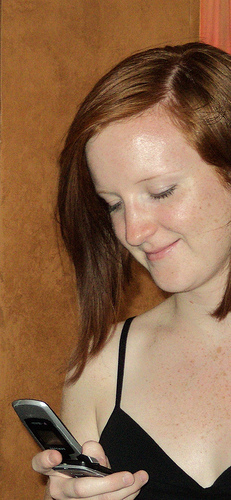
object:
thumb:
[80, 439, 107, 470]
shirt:
[97, 317, 231, 500]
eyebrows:
[97, 190, 115, 197]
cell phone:
[11, 398, 112, 480]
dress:
[98, 314, 231, 499]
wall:
[2, 8, 114, 100]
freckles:
[138, 126, 229, 452]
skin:
[31, 104, 229, 499]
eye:
[149, 183, 176, 199]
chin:
[149, 250, 196, 294]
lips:
[143, 237, 180, 263]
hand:
[31, 450, 150, 500]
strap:
[114, 317, 138, 413]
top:
[98, 315, 231, 499]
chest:
[95, 323, 229, 498]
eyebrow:
[135, 174, 163, 185]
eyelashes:
[149, 185, 176, 200]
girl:
[32, 42, 230, 498]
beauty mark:
[198, 205, 201, 210]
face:
[85, 113, 231, 286]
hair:
[52, 42, 229, 389]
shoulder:
[61, 293, 175, 409]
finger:
[30, 448, 62, 475]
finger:
[69, 469, 149, 499]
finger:
[65, 471, 134, 499]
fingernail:
[49, 450, 60, 463]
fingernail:
[122, 472, 135, 486]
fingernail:
[136, 469, 149, 482]